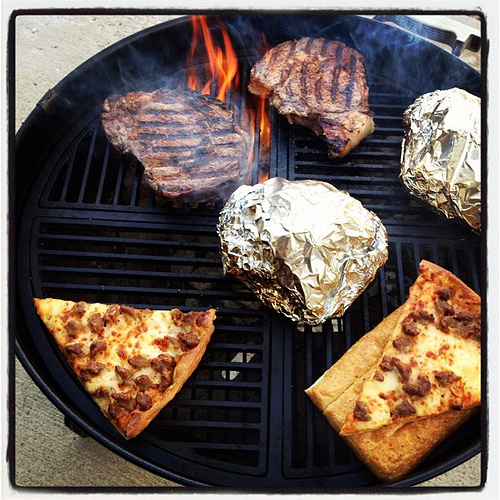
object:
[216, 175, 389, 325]
potato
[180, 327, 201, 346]
sausage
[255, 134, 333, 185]
metal grill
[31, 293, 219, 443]
pizza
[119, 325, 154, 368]
cheese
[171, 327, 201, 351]
sausage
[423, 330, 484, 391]
cheese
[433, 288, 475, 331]
sausage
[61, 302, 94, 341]
sausage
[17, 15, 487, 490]
grill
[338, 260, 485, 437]
pizza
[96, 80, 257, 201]
barbeque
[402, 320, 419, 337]
sausage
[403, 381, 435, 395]
sausage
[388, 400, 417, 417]
sausage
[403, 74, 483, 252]
foil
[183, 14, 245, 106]
fire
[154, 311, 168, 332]
cheese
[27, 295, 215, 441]
breadsticks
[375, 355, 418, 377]
sausage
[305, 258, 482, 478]
breadsticks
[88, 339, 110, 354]
topping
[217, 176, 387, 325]
foil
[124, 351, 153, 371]
sausage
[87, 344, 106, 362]
sausage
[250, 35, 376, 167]
food